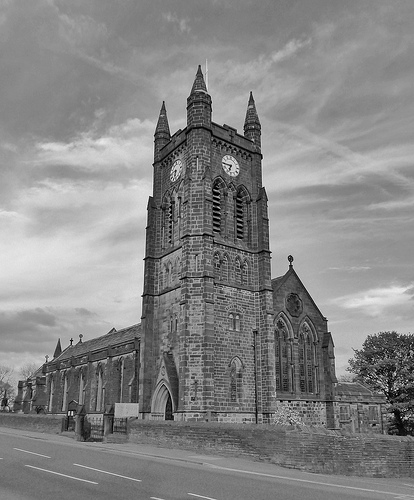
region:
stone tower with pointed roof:
[180, 59, 214, 123]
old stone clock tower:
[141, 66, 275, 439]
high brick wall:
[0, 414, 412, 470]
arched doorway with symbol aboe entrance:
[144, 348, 183, 440]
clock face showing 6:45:
[215, 149, 242, 176]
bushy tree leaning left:
[344, 328, 412, 461]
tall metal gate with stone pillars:
[73, 411, 129, 444]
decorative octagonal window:
[282, 289, 306, 322]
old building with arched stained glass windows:
[275, 248, 340, 440]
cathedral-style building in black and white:
[5, 8, 410, 493]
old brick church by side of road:
[42, 47, 336, 480]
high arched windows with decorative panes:
[256, 302, 324, 421]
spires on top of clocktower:
[111, 50, 276, 239]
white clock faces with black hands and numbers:
[160, 145, 256, 202]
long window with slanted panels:
[201, 173, 254, 263]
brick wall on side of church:
[21, 375, 401, 477]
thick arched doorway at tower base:
[134, 341, 215, 438]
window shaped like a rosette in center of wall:
[260, 282, 321, 324]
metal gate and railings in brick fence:
[51, 393, 139, 442]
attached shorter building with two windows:
[312, 367, 384, 431]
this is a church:
[152, 105, 264, 401]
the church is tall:
[133, 77, 270, 414]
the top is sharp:
[193, 62, 201, 81]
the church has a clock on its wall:
[222, 154, 239, 176]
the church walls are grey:
[143, 65, 258, 418]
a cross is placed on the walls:
[225, 132, 236, 142]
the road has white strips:
[21, 456, 146, 486]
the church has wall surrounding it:
[186, 429, 378, 455]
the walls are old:
[135, 57, 262, 441]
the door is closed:
[159, 393, 177, 419]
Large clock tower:
[139, 53, 280, 450]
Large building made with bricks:
[30, 57, 384, 423]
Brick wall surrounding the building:
[121, 414, 409, 482]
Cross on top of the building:
[62, 330, 82, 355]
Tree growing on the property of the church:
[344, 311, 412, 424]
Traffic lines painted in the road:
[8, 442, 163, 489]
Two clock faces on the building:
[159, 147, 251, 188]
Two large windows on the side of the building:
[275, 305, 330, 397]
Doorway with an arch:
[141, 370, 184, 443]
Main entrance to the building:
[73, 380, 188, 458]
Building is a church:
[6, 56, 404, 456]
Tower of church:
[125, 50, 292, 429]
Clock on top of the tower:
[216, 150, 243, 181]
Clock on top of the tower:
[162, 154, 187, 188]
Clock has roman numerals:
[215, 150, 243, 179]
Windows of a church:
[262, 302, 330, 404]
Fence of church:
[0, 403, 413, 490]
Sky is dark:
[7, 4, 412, 339]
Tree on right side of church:
[346, 327, 412, 429]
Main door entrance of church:
[144, 376, 181, 425]